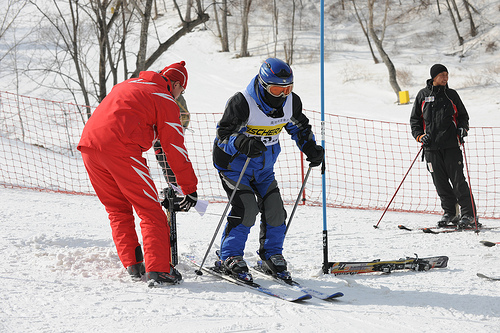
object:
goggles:
[258, 81, 296, 95]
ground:
[0, 208, 500, 333]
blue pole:
[318, 2, 330, 278]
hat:
[161, 59, 191, 89]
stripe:
[165, 68, 184, 80]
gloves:
[227, 132, 267, 160]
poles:
[282, 160, 317, 239]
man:
[407, 62, 479, 227]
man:
[74, 62, 194, 283]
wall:
[314, 136, 353, 173]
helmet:
[258, 56, 292, 104]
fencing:
[0, 89, 500, 222]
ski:
[183, 249, 346, 302]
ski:
[373, 220, 500, 233]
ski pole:
[452, 134, 479, 222]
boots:
[212, 249, 252, 280]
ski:
[320, 255, 450, 275]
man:
[210, 58, 327, 283]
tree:
[15, 0, 208, 122]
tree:
[208, 0, 233, 52]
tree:
[233, 0, 251, 56]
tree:
[346, 0, 411, 105]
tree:
[274, 1, 295, 66]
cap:
[426, 62, 449, 79]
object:
[397, 87, 411, 103]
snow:
[1, 0, 499, 331]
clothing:
[408, 78, 480, 226]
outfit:
[75, 70, 199, 288]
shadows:
[183, 275, 500, 317]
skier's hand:
[228, 134, 266, 159]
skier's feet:
[256, 245, 291, 280]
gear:
[72, 61, 199, 290]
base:
[320, 227, 331, 275]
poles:
[373, 142, 428, 228]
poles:
[195, 156, 253, 281]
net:
[326, 116, 406, 219]